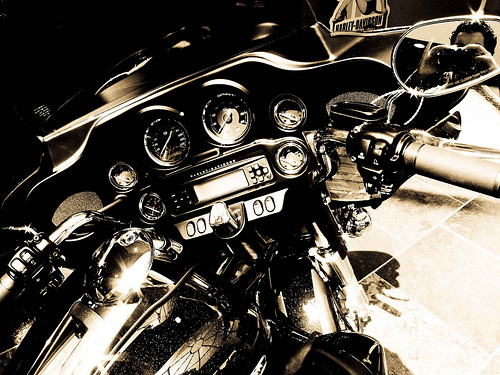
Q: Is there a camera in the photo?
A: Yes, there is a camera.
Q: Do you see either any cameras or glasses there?
A: Yes, there is a camera.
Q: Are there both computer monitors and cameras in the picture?
A: No, there is a camera but no computer monitors.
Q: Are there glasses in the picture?
A: No, there are no glasses.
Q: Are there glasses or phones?
A: No, there are no glasses or phones.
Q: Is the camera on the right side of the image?
A: Yes, the camera is on the right of the image.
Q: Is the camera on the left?
A: No, the camera is on the right of the image.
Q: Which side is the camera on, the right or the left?
A: The camera is on the right of the image.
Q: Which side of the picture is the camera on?
A: The camera is on the right of the image.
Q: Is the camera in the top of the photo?
A: Yes, the camera is in the top of the image.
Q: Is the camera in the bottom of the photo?
A: No, the camera is in the top of the image.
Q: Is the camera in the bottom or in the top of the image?
A: The camera is in the top of the image.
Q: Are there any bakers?
A: No, there are no bakers.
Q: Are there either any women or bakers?
A: No, there are no bakers or women.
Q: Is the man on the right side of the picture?
A: Yes, the man is on the right of the image.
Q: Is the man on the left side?
A: No, the man is on the right of the image.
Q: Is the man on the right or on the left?
A: The man is on the right of the image.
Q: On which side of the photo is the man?
A: The man is on the right of the image.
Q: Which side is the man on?
A: The man is on the right of the image.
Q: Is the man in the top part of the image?
A: Yes, the man is in the top of the image.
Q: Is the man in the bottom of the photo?
A: No, the man is in the top of the image.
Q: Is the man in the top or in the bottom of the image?
A: The man is in the top of the image.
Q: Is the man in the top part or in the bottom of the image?
A: The man is in the top of the image.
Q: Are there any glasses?
A: No, there are no glasses.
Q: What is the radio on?
A: The radio is on the bike.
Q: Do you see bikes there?
A: Yes, there is a bike.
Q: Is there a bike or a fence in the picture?
A: Yes, there is a bike.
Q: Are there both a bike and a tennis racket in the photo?
A: No, there is a bike but no rackets.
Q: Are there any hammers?
A: No, there are no hammers.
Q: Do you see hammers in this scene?
A: No, there are no hammers.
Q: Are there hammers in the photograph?
A: No, there are no hammers.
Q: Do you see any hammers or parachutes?
A: No, there are no hammers or parachutes.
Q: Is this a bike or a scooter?
A: This is a bike.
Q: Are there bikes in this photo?
A: Yes, there is a bike.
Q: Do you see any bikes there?
A: Yes, there is a bike.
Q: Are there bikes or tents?
A: Yes, there is a bike.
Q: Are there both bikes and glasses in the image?
A: No, there is a bike but no glasses.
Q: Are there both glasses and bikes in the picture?
A: No, there is a bike but no glasses.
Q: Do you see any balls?
A: No, there are no balls.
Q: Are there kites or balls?
A: No, there are no balls or kites.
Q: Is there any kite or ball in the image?
A: No, there are no balls or kites.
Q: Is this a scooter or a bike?
A: This is a bike.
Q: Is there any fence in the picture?
A: No, there are no fences.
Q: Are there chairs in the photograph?
A: No, there are no chairs.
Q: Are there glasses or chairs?
A: No, there are no chairs or glasses.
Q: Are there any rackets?
A: No, there are no rackets.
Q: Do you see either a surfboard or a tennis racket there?
A: No, there are no rackets or surfboards.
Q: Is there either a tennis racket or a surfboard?
A: No, there are no rackets or surfboards.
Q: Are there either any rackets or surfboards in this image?
A: No, there are no rackets or surfboards.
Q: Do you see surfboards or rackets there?
A: No, there are no rackets or surfboards.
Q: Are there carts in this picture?
A: No, there are no carts.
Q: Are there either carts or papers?
A: No, there are no carts or papers.